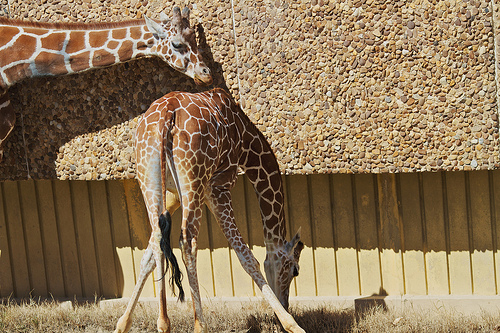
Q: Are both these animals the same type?
A: Yes, all the animals are giraffes.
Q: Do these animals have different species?
A: No, all the animals are giraffes.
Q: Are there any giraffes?
A: Yes, there is a giraffe.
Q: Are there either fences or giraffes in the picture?
A: Yes, there is a giraffe.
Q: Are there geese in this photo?
A: No, there are no geese.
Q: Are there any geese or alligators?
A: No, there are no geese or alligators.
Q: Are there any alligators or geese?
A: No, there are no geese or alligators.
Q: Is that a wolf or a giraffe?
A: That is a giraffe.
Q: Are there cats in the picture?
A: No, there are no cats.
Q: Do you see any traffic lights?
A: No, there are no traffic lights.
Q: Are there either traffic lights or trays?
A: No, there are no traffic lights or trays.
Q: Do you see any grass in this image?
A: Yes, there is grass.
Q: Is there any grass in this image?
A: Yes, there is grass.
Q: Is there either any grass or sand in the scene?
A: Yes, there is grass.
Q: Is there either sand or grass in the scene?
A: Yes, there is grass.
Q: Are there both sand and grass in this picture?
A: No, there is grass but no sand.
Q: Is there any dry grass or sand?
A: Yes, there is dry grass.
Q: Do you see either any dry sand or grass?
A: Yes, there is dry grass.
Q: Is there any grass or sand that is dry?
A: Yes, the grass is dry.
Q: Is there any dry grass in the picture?
A: Yes, there is dry grass.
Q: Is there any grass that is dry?
A: Yes, there is grass that is dry.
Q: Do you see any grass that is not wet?
A: Yes, there is dry grass.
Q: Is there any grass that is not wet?
A: Yes, there is dry grass.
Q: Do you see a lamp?
A: No, there are no lamps.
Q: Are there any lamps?
A: No, there are no lamps.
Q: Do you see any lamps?
A: No, there are no lamps.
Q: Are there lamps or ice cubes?
A: No, there are no lamps or ice cubes.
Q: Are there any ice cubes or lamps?
A: No, there are no lamps or ice cubes.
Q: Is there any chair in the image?
A: No, there are no chairs.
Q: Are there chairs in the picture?
A: No, there are no chairs.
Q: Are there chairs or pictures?
A: No, there are no chairs or pictures.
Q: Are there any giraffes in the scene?
A: Yes, there is a giraffe.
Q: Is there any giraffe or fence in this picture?
A: Yes, there is a giraffe.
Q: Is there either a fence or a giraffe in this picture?
A: Yes, there is a giraffe.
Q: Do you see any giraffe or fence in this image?
A: Yes, there is a giraffe.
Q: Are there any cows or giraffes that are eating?
A: Yes, the giraffe is eating.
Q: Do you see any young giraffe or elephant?
A: Yes, there is a young giraffe.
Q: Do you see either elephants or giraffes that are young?
A: Yes, the giraffe is young.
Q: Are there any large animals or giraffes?
A: Yes, there is a large giraffe.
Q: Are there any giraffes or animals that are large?
A: Yes, the giraffe is large.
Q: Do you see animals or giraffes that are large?
A: Yes, the giraffe is large.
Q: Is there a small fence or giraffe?
A: Yes, there is a small giraffe.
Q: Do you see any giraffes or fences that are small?
A: Yes, the giraffe is small.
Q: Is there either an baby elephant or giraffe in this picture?
A: Yes, there is a baby giraffe.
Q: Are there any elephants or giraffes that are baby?
A: Yes, the giraffe is a baby.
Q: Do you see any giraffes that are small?
A: Yes, there is a small giraffe.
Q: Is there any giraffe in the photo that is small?
A: Yes, there is a giraffe that is small.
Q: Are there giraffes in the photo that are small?
A: Yes, there is a giraffe that is small.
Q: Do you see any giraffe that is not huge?
A: Yes, there is a small giraffe.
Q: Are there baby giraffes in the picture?
A: Yes, there is a baby giraffe.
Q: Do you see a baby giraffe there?
A: Yes, there is a baby giraffe.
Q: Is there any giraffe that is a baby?
A: Yes, there is a giraffe that is a baby.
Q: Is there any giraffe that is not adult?
A: Yes, there is an baby giraffe.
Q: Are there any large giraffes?
A: Yes, there is a large giraffe.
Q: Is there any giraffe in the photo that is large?
A: Yes, there is a giraffe that is large.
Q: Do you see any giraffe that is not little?
A: Yes, there is a large giraffe.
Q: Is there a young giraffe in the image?
A: Yes, there is a young giraffe.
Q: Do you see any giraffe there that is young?
A: Yes, there is a giraffe that is young.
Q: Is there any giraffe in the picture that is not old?
A: Yes, there is an young giraffe.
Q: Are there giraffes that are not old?
A: Yes, there is an young giraffe.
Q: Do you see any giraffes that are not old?
A: Yes, there is an young giraffe.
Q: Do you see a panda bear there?
A: No, there are no pandas.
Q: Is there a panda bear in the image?
A: No, there are no pandas.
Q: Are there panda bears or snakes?
A: No, there are no panda bears or snakes.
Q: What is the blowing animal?
A: The animal is a giraffe.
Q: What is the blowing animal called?
A: The animal is a giraffe.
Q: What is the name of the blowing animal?
A: The animal is a giraffe.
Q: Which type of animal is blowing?
A: The animal is a giraffe.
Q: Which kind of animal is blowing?
A: The animal is a giraffe.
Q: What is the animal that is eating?
A: The animal is a giraffe.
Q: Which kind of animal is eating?
A: The animal is a giraffe.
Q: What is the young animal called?
A: The animal is a giraffe.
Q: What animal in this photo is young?
A: The animal is a giraffe.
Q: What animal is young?
A: The animal is a giraffe.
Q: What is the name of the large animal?
A: The animal is a giraffe.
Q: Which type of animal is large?
A: The animal is a giraffe.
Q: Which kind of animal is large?
A: The animal is a giraffe.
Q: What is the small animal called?
A: The animal is a giraffe.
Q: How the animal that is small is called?
A: The animal is a giraffe.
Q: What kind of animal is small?
A: The animal is a giraffe.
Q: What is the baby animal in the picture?
A: The animal is a giraffe.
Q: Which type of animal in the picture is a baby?
A: The animal is a giraffe.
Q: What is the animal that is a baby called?
A: The animal is a giraffe.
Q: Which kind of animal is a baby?
A: The animal is a giraffe.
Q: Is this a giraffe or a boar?
A: This is a giraffe.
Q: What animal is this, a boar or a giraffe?
A: This is a giraffe.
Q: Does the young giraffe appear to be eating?
A: Yes, the giraffe is eating.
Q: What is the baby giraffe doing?
A: The giraffe is eating.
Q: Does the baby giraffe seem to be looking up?
A: No, the giraffe is eating.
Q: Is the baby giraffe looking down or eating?
A: The giraffe is eating.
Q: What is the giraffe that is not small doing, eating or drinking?
A: The giraffe is eating.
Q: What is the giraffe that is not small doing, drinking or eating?
A: The giraffe is eating.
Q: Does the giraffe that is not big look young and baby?
A: Yes, the giraffe is young and baby.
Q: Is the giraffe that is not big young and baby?
A: Yes, the giraffe is young and baby.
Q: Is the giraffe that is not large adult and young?
A: No, the giraffe is young but baby.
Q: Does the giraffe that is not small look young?
A: Yes, the giraffe is young.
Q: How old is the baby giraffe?
A: The giraffe is young.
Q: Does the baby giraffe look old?
A: No, the giraffe is young.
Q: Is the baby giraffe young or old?
A: The giraffe is young.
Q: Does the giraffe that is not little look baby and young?
A: Yes, the giraffe is a baby and young.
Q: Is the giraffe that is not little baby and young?
A: Yes, the giraffe is a baby and young.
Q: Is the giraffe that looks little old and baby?
A: No, the giraffe is a baby but young.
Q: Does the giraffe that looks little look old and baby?
A: No, the giraffe is a baby but young.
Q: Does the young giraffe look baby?
A: Yes, the giraffe is a baby.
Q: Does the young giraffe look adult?
A: No, the giraffe is a baby.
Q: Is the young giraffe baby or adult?
A: The giraffe is a baby.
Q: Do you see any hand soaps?
A: No, there are no hand soaps.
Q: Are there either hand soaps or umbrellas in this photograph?
A: No, there are no hand soaps or umbrellas.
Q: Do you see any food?
A: Yes, there is food.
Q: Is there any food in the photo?
A: Yes, there is food.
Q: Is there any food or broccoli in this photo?
A: Yes, there is food.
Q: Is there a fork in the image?
A: No, there are no forks.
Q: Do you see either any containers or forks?
A: No, there are no forks or containers.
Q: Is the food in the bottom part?
A: Yes, the food is in the bottom of the image.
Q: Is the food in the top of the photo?
A: No, the food is in the bottom of the image.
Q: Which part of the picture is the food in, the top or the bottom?
A: The food is in the bottom of the image.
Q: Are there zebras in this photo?
A: No, there are no zebras.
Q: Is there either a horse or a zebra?
A: No, there are no zebras or horses.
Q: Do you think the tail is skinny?
A: Yes, the tail is skinny.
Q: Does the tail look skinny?
A: Yes, the tail is skinny.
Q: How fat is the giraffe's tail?
A: The tail is skinny.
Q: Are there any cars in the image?
A: No, there are no cars.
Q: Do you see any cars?
A: No, there are no cars.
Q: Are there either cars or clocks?
A: No, there are no cars or clocks.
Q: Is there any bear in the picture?
A: No, there are no bears.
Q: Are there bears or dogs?
A: No, there are no bears or dogs.